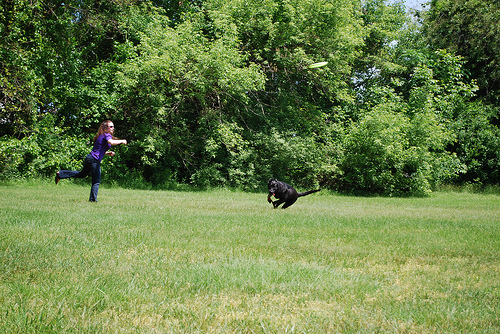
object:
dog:
[264, 175, 321, 209]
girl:
[54, 119, 128, 203]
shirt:
[87, 134, 112, 161]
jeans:
[59, 154, 102, 202]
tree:
[68, 20, 280, 137]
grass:
[126, 210, 458, 312]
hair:
[94, 119, 106, 139]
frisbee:
[306, 61, 331, 69]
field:
[4, 4, 499, 333]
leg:
[60, 158, 90, 184]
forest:
[2, 2, 498, 177]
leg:
[89, 162, 102, 202]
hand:
[122, 139, 127, 146]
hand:
[109, 151, 116, 157]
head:
[104, 120, 115, 134]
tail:
[298, 188, 321, 197]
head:
[268, 180, 279, 194]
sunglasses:
[110, 126, 115, 128]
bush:
[260, 134, 420, 186]